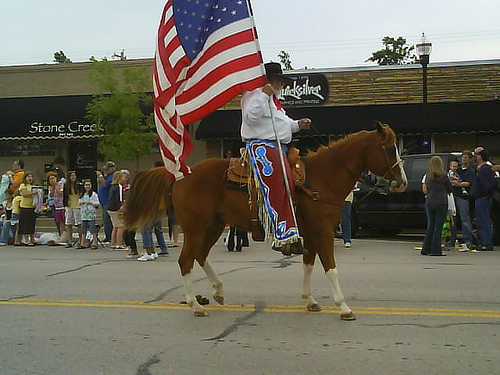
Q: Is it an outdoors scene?
A: Yes, it is outdoors.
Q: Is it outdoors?
A: Yes, it is outdoors.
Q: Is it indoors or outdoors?
A: It is outdoors.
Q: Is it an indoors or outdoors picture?
A: It is outdoors.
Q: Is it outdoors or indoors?
A: It is outdoors.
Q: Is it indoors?
A: No, it is outdoors.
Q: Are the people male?
A: No, they are both male and female.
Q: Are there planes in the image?
A: No, there are no planes.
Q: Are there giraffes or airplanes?
A: No, there are no airplanes or giraffes.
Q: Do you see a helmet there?
A: No, there are no helmets.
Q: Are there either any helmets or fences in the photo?
A: No, there are no helmets or fences.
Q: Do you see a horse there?
A: Yes, there is a horse.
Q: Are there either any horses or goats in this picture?
A: Yes, there is a horse.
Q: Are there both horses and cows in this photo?
A: No, there is a horse but no cows.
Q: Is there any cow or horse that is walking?
A: Yes, the horse is walking.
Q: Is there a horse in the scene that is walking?
A: Yes, there is a horse that is walking.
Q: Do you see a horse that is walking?
A: Yes, there is a horse that is walking.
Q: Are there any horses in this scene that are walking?
A: Yes, there is a horse that is walking.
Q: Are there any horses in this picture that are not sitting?
A: Yes, there is a horse that is walking.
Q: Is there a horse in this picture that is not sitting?
A: Yes, there is a horse that is walking.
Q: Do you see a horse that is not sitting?
A: Yes, there is a horse that is walking .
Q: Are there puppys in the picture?
A: No, there are no puppys.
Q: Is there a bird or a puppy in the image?
A: No, there are no puppys or birds.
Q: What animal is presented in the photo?
A: The animal is a horse.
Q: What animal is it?
A: The animal is a horse.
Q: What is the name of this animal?
A: This is a horse.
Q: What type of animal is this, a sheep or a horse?
A: This is a horse.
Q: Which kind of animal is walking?
A: The animal is a horse.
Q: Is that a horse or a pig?
A: That is a horse.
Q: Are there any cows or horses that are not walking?
A: No, there is a horse but it is walking.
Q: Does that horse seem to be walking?
A: Yes, the horse is walking.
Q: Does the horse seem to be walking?
A: Yes, the horse is walking.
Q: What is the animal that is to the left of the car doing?
A: The horse is walking.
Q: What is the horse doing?
A: The horse is walking.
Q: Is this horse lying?
A: No, the horse is walking.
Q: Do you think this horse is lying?
A: No, the horse is walking.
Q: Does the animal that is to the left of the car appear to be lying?
A: No, the horse is walking.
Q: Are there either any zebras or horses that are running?
A: No, there is a horse but it is walking.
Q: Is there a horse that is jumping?
A: No, there is a horse but it is walking.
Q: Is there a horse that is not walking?
A: No, there is a horse but it is walking.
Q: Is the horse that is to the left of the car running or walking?
A: The horse is walking.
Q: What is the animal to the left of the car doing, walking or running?
A: The horse is walking.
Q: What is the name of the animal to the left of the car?
A: The animal is a horse.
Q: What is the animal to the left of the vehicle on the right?
A: The animal is a horse.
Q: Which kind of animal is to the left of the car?
A: The animal is a horse.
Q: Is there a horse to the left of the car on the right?
A: Yes, there is a horse to the left of the car.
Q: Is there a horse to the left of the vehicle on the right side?
A: Yes, there is a horse to the left of the car.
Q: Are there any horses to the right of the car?
A: No, the horse is to the left of the car.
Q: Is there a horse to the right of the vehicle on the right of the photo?
A: No, the horse is to the left of the car.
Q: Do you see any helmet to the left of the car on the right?
A: No, there is a horse to the left of the car.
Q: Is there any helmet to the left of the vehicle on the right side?
A: No, there is a horse to the left of the car.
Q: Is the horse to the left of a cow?
A: No, the horse is to the left of the car.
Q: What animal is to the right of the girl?
A: The animal is a horse.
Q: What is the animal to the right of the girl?
A: The animal is a horse.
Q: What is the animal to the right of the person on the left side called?
A: The animal is a horse.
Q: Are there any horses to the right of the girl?
A: Yes, there is a horse to the right of the girl.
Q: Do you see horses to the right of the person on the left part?
A: Yes, there is a horse to the right of the girl.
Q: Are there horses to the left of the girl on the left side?
A: No, the horse is to the right of the girl.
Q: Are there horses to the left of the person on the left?
A: No, the horse is to the right of the girl.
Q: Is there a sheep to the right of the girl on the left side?
A: No, there is a horse to the right of the girl.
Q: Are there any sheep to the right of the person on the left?
A: No, there is a horse to the right of the girl.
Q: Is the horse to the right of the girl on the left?
A: Yes, the horse is to the right of the girl.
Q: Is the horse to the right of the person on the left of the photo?
A: Yes, the horse is to the right of the girl.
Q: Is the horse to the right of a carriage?
A: No, the horse is to the right of the girl.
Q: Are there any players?
A: No, there are no players.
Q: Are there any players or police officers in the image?
A: No, there are no players or police officers.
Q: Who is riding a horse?
A: The man is riding a horse.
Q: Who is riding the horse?
A: The man is riding a horse.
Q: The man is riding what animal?
A: The man is riding a horse.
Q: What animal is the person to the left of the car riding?
A: The man is riding a horse.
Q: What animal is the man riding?
A: The man is riding a horse.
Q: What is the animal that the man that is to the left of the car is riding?
A: The animal is a horse.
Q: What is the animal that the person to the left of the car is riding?
A: The animal is a horse.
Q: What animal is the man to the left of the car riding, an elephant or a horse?
A: The man is riding a horse.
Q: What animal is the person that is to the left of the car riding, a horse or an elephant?
A: The man is riding a horse.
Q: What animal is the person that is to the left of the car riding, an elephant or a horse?
A: The man is riding a horse.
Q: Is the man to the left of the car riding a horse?
A: Yes, the man is riding a horse.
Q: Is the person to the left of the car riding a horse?
A: Yes, the man is riding a horse.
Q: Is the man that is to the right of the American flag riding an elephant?
A: No, the man is riding a horse.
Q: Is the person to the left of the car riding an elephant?
A: No, the man is riding a horse.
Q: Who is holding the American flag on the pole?
A: The man is holding the American flag.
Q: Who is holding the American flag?
A: The man is holding the American flag.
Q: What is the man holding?
A: The man is holding the American flag.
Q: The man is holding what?
A: The man is holding the American flag.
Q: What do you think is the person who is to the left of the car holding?
A: The man is holding the American flag.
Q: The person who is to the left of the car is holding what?
A: The man is holding the American flag.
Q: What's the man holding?
A: The man is holding the American flag.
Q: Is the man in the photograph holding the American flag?
A: Yes, the man is holding the American flag.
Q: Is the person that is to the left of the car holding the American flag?
A: Yes, the man is holding the American flag.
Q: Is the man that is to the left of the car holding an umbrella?
A: No, the man is holding the American flag.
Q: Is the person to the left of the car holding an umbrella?
A: No, the man is holding the American flag.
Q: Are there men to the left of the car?
A: Yes, there is a man to the left of the car.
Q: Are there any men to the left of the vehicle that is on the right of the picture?
A: Yes, there is a man to the left of the car.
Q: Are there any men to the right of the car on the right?
A: No, the man is to the left of the car.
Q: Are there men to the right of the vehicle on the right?
A: No, the man is to the left of the car.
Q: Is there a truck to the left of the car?
A: No, there is a man to the left of the car.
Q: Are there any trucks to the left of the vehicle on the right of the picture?
A: No, there is a man to the left of the car.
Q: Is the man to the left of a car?
A: Yes, the man is to the left of a car.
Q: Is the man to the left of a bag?
A: No, the man is to the left of a car.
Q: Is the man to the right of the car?
A: No, the man is to the left of the car.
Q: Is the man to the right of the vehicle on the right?
A: No, the man is to the left of the car.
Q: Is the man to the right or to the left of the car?
A: The man is to the left of the car.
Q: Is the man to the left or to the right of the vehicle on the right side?
A: The man is to the left of the car.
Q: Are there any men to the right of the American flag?
A: Yes, there is a man to the right of the American flag.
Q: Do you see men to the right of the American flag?
A: Yes, there is a man to the right of the American flag.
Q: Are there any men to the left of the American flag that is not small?
A: No, the man is to the right of the American flag.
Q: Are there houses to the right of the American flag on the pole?
A: No, there is a man to the right of the American flag.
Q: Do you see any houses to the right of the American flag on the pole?
A: No, there is a man to the right of the American flag.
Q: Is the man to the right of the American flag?
A: Yes, the man is to the right of the American flag.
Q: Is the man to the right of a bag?
A: No, the man is to the right of the American flag.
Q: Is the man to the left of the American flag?
A: No, the man is to the right of the American flag.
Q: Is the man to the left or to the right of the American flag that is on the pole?
A: The man is to the right of the American flag.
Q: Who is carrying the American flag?
A: The man is carrying the American flag.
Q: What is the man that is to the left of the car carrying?
A: The man is carrying an American flag.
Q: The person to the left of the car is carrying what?
A: The man is carrying an American flag.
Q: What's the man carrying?
A: The man is carrying an American flag.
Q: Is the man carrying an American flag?
A: Yes, the man is carrying an American flag.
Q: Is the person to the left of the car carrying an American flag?
A: Yes, the man is carrying an American flag.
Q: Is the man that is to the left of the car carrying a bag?
A: No, the man is carrying an American flag.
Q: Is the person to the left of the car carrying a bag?
A: No, the man is carrying an American flag.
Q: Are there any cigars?
A: No, there are no cigars.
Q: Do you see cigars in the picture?
A: No, there are no cigars.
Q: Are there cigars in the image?
A: No, there are no cigars.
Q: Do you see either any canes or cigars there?
A: No, there are no cigars or canes.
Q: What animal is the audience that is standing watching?
A: The audience is watching the horse.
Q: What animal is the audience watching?
A: The audience is watching the horse.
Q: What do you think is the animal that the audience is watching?
A: The animal is a horse.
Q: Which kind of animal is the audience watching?
A: The audience is watching the horse.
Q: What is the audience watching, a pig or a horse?
A: The audience is watching a horse.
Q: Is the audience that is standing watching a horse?
A: Yes, the audience is watching a horse.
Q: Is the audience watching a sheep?
A: No, the audience is watching a horse.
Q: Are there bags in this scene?
A: No, there are no bags.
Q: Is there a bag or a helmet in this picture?
A: No, there are no bags or helmets.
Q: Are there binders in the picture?
A: No, there are no binders.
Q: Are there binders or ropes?
A: No, there are no binders or ropes.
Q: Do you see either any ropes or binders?
A: No, there are no binders or ropes.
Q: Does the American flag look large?
A: Yes, the American flag is large.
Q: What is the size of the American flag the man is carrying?
A: The American flag is large.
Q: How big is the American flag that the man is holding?
A: The American flag is large.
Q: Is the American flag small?
A: No, the American flag is large.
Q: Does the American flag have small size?
A: No, the American flag is large.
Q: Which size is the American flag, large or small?
A: The American flag is large.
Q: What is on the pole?
A: The American flag is on the pole.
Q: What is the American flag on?
A: The American flag is on the pole.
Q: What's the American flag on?
A: The American flag is on the pole.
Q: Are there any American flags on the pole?
A: Yes, there is an American flag on the pole.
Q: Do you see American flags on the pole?
A: Yes, there is an American flag on the pole.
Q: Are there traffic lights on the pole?
A: No, there is an American flag on the pole.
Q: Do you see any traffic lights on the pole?
A: No, there is an American flag on the pole.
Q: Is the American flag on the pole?
A: Yes, the American flag is on the pole.